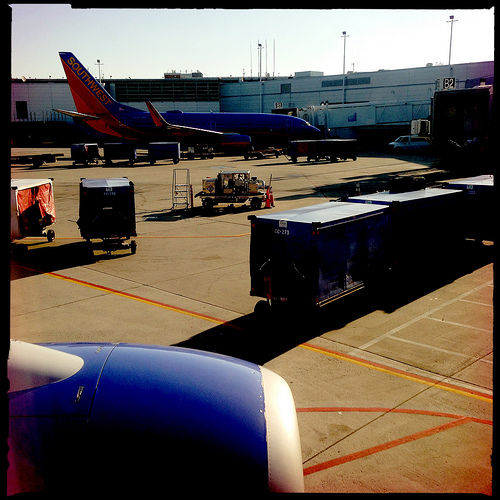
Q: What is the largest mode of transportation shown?
A: Plane.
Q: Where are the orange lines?
A: Pavement.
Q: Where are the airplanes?
A: Tarmac.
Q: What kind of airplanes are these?
A: Red and blue airplanes.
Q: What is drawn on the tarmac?
A: Orange and white lines.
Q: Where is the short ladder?
A: In the middle of the photo in front of the airplane.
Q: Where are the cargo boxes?
A: On the right side of screen.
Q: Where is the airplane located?
A: Airport.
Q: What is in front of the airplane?
A: Building.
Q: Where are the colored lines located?
A: Ground.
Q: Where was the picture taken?
A: Airport.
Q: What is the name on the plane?
A: Southwest.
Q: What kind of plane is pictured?
A: Passenger.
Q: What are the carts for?
A: Luggage.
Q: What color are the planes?
A: Blue.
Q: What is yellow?
A: Street lines.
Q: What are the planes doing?
A: Parked.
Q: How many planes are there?
A: Two.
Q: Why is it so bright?
A: Sun light.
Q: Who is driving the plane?
A: The pilot.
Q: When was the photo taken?
A: Day time.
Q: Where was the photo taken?
A: On the tarmac.